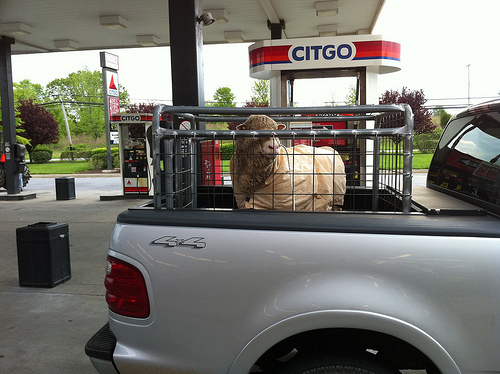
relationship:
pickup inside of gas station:
[82, 99, 499, 373] [0, 1, 437, 373]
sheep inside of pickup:
[227, 112, 348, 212] [82, 99, 499, 373]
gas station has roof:
[0, 1, 437, 373] [1, 0, 385, 55]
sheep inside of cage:
[227, 112, 348, 212] [151, 104, 414, 214]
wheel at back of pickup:
[273, 346, 407, 373] [82, 99, 499, 373]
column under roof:
[168, 0, 203, 187] [1, 0, 385, 55]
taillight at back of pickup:
[103, 253, 150, 318] [82, 99, 499, 373]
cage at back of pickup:
[151, 104, 414, 214] [82, 99, 499, 373]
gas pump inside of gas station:
[248, 35, 401, 190] [0, 1, 437, 373]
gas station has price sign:
[0, 1, 437, 373] [109, 95, 120, 116]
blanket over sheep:
[230, 145, 348, 214] [227, 112, 348, 212]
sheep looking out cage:
[227, 112, 348, 212] [151, 104, 414, 214]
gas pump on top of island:
[106, 111, 154, 194] [98, 190, 154, 202]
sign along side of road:
[104, 70, 122, 97] [21, 141, 438, 188]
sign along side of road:
[109, 95, 120, 116] [21, 141, 438, 188]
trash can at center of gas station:
[14, 220, 74, 288] [0, 1, 437, 373]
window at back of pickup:
[427, 105, 499, 203] [82, 99, 499, 373]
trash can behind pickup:
[14, 220, 74, 288] [82, 99, 499, 373]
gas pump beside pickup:
[248, 35, 401, 190] [82, 99, 499, 373]